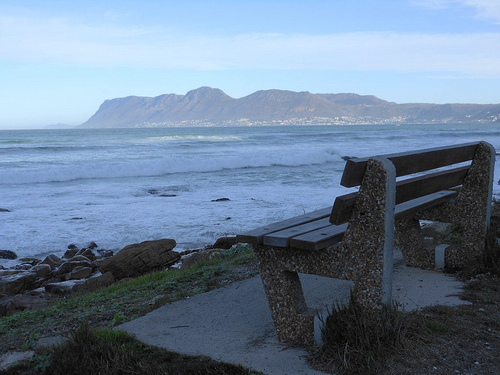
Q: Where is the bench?
A: At the shoreline.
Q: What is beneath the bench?
A: A slab of smooth concrete.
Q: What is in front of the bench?
A: Rocks.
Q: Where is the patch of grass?
A: Beside the bench.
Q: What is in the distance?
A: Mountains.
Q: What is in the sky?
A: Clouds.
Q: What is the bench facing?
A: The sea.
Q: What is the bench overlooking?
A: Water.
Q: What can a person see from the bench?
A: The mountain.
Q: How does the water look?
A: Calm.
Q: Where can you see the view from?
A: The bench.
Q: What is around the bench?
A: Concrete.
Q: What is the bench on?
A: Cement.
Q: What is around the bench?
A: Grasses.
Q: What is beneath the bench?
A: A patch of grass.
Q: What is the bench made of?
A: Concrete and wood.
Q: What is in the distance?
A: Mountains.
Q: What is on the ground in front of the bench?
A: Rocks.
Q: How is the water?
A: Calm.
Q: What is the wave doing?
A: Rolling.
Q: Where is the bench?
A: At the beach.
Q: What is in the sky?
A: Clouds.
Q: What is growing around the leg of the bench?
A: Plants.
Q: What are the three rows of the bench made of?
A: Wood.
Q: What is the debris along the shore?
A: Rocks.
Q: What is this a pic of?
A: A park bench by the sea.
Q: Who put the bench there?
A: The people.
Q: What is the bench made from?
A: Concrete.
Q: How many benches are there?
A: 1.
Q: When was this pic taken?
A: At dusk.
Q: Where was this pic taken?
A: Near the sea.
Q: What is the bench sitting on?
A: Cement platform.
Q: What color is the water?
A: Blue.